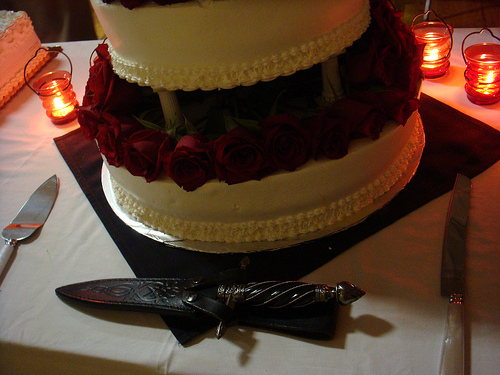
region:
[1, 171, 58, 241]
the blade of a pie cutter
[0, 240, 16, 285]
the handle of a pie cutter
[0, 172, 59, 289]
a metal pie cutter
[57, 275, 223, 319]
a black leather sheath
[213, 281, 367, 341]
a black knife handle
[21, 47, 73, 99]
a round candle handle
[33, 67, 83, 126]
a clear candle holder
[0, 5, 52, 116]
a rectangular cake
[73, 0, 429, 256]
a large round cake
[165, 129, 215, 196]
a red rose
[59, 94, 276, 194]
the roses are red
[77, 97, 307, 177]
the roses are on the cake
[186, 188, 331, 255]
the cake is white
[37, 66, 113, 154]
the candle is on a lamp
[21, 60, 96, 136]
the lamp is red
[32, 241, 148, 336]
the tablecloth is white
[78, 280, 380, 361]
the dagger is on the table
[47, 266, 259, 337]
the dagger holder is made of leather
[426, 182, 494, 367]
the cake knife is on the table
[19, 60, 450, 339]
the cake is on the table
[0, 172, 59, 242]
the blade of the pie cutter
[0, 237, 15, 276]
the white handle of the pie cutter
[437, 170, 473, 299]
a silver knife blade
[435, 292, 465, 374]
a white knife handle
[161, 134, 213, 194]
a red rose on the cake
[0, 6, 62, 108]
a white rectangular cake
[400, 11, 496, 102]
two candles behind the cake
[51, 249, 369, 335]
knife laying in front of the cake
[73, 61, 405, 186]
roses around the tier of the cake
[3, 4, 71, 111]
edge of a cake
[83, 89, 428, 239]
bottom layer of the cake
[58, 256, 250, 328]
sheath covering the knife blade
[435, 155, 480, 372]
knife with ivory handle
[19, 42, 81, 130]
orange candle to the left of the cake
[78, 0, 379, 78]
top layer of the cake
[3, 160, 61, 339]
cake serving knife on the table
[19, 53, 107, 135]
tea light votive candle in jar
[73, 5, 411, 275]
wedding cake with roses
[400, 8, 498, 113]
decorative votive tea light candles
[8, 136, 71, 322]
wedding cake serving spatula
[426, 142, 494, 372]
wedding cake knife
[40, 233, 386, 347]
black knife case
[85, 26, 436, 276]
two tier wedding cake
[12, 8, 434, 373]
wedding cake on a table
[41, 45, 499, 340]
black napkin under a wedding cake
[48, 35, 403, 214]
roses on a wedding cake